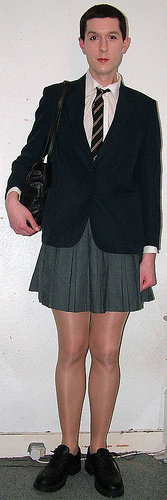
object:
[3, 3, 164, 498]
man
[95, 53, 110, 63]
lipstick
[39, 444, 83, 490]
shoes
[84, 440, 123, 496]
shoe strings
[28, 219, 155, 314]
skirt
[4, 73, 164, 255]
jacket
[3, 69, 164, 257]
shirt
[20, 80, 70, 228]
purse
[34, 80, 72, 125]
shoulder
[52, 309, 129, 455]
stockings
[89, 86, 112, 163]
tie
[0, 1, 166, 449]
wall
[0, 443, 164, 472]
something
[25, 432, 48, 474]
outlet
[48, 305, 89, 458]
legs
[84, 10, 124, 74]
face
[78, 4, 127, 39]
hair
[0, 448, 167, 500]
carpet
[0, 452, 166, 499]
floor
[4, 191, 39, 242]
hand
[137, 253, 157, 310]
fist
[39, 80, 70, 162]
straps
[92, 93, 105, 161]
stripes